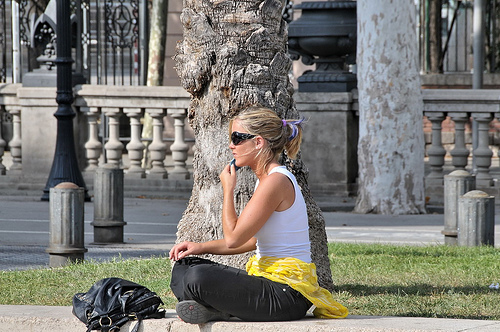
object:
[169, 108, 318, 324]
woman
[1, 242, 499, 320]
grass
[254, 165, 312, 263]
shirt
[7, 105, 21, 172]
pillar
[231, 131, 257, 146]
sunglasses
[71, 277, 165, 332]
handbag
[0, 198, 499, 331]
ground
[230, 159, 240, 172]
phone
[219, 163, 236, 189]
hand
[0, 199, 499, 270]
road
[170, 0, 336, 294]
tree trunk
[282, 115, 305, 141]
hair tie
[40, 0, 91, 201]
lamp post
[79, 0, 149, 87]
gate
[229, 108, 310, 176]
hair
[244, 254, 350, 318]
clothing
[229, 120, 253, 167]
woman's face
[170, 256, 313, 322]
pants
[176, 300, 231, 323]
shoe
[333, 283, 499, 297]
shadow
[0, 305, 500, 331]
curb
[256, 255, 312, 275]
woman's waist